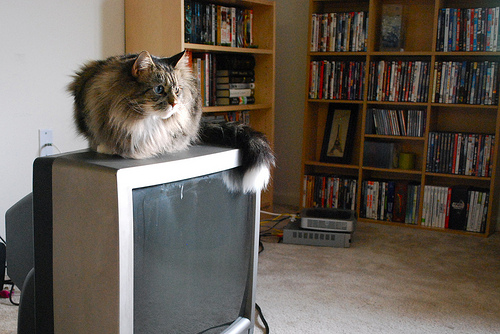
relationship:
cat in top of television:
[67, 42, 222, 158] [26, 143, 262, 333]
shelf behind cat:
[125, 1, 279, 138] [67, 42, 222, 158]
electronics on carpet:
[272, 206, 360, 251] [264, 246, 495, 334]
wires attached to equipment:
[259, 203, 284, 246] [272, 206, 360, 251]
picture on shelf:
[315, 99, 357, 167] [301, 2, 498, 238]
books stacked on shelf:
[211, 56, 257, 105] [125, 1, 279, 138]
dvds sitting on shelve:
[310, 10, 366, 51] [301, 2, 498, 238]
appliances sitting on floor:
[272, 206, 360, 251] [264, 246, 495, 334]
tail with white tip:
[199, 106, 277, 195] [238, 166, 271, 198]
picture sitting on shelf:
[315, 99, 357, 167] [301, 2, 498, 238]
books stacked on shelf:
[186, 53, 260, 107] [125, 1, 279, 138]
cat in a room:
[67, 42, 222, 158] [4, 3, 499, 331]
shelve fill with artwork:
[301, 2, 498, 238] [315, 99, 357, 167]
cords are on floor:
[259, 203, 284, 246] [267, 218, 498, 333]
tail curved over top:
[199, 106, 277, 195] [101, 138, 238, 161]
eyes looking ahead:
[153, 82, 181, 96] [400, 4, 499, 333]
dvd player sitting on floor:
[272, 206, 360, 251] [267, 218, 498, 333]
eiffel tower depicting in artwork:
[326, 122, 344, 155] [315, 99, 357, 167]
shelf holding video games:
[301, 2, 498, 238] [368, 60, 429, 103]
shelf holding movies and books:
[125, 1, 279, 138] [189, 7, 260, 118]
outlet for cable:
[35, 125, 55, 154] [43, 141, 63, 153]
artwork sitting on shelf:
[315, 99, 357, 167] [301, 2, 498, 238]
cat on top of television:
[67, 42, 222, 158] [26, 143, 262, 333]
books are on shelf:
[211, 56, 257, 105] [125, 1, 279, 138]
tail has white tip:
[199, 106, 277, 195] [238, 166, 271, 198]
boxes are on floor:
[272, 206, 360, 251] [267, 218, 498, 333]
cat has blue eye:
[67, 42, 222, 158] [152, 81, 168, 97]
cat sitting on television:
[67, 42, 222, 158] [0, 146, 264, 334]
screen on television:
[130, 164, 253, 334] [0, 146, 264, 334]